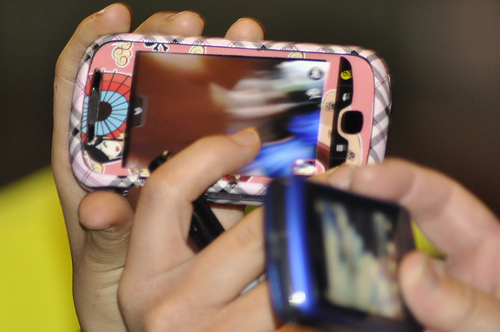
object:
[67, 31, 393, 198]
trim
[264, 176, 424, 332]
camera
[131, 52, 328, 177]
coral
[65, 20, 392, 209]
cell phone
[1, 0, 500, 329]
yellow patch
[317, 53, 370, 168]
panel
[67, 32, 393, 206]
cell phone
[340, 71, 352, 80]
button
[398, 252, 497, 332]
finger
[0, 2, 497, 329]
somebody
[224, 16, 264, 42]
finger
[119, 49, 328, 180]
screen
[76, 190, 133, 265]
finger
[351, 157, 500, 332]
hand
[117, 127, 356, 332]
hand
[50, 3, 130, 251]
finger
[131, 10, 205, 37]
finger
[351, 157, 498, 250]
finger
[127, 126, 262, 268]
finger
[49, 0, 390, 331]
hand